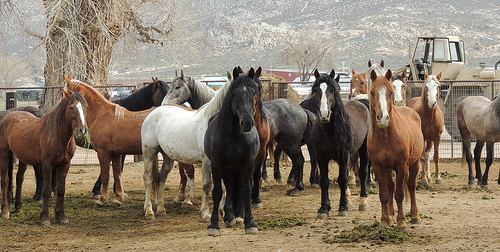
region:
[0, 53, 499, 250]
The horses are gathered together.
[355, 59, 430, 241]
The horse is brown and white.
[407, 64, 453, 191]
The horse is brown and white.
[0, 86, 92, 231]
The horse is brown and white.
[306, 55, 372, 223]
The horse is dark brown and white.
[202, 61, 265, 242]
The horse is black.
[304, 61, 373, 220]
The horse is alert.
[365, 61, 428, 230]
The horse is alert.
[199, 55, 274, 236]
The horse is alert.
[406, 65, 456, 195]
The horse is alert.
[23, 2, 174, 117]
large tree standing behind horse enclosure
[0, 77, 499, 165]
fence around horse enclosure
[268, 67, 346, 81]
a red metal building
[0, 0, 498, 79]
a hill behind a horse enclosure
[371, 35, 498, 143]
a piece of heavy machinery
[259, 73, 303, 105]
a bale of hay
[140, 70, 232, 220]
white horse in an enclosure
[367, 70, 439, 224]
three brown horses with white stripes on their nose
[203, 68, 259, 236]
a black horse standing in an enclosure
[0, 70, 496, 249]
several horses inside a fence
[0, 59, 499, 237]
A group of horses in a corral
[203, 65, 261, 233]
A black horse in a corral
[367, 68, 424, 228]
A brown horse with a whitemark on its face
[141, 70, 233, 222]
The back part of a white horse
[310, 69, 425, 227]
Two horses standing almost next to one another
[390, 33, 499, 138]
A tan colored tractor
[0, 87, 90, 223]
A brown horse eating hay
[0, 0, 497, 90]
A mountain visible on the background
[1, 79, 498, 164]
The fence of a corral for horses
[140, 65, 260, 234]
A black horse standing in front of a white horse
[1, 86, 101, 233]
The horse is eating something.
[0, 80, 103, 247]
The horse has something in its mouth.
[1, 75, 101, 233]
The horse is standing.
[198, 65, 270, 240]
The horse is standing.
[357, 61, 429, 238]
The horse is standing.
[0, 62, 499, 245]
Horses in a fence.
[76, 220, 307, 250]
The ground is brown.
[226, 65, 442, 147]
The horses are looking at the camera.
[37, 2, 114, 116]
Tree outside of the fence.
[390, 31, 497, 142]
Tractor outside of the fence.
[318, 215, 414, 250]
Hay on the ground.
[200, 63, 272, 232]
The horse is black.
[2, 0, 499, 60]
Mountain in the background.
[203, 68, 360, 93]
The buildings are red and white.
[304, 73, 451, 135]
White on the horses' faces.